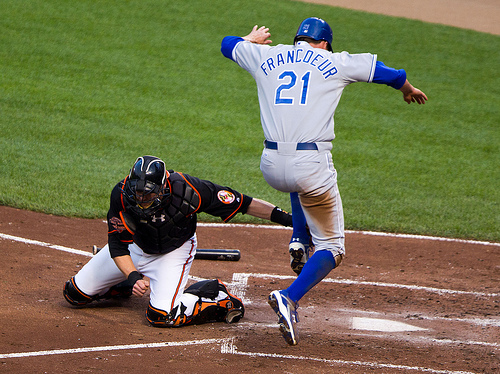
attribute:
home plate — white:
[351, 305, 433, 343]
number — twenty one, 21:
[275, 64, 315, 114]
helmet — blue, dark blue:
[292, 14, 337, 45]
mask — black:
[122, 182, 168, 219]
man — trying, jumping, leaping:
[209, 13, 458, 342]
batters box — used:
[223, 257, 497, 374]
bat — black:
[183, 246, 244, 262]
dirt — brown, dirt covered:
[2, 207, 499, 368]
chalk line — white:
[3, 337, 228, 355]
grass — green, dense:
[4, 1, 500, 234]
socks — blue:
[281, 249, 336, 317]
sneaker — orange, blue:
[212, 277, 257, 317]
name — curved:
[255, 48, 340, 82]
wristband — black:
[123, 271, 146, 293]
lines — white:
[183, 262, 282, 367]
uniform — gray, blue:
[208, 38, 413, 334]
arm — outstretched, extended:
[177, 172, 298, 243]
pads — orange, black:
[147, 276, 235, 334]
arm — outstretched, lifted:
[335, 51, 434, 112]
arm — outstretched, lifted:
[215, 17, 280, 75]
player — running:
[211, 10, 439, 354]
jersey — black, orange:
[100, 168, 248, 261]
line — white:
[4, 230, 93, 257]